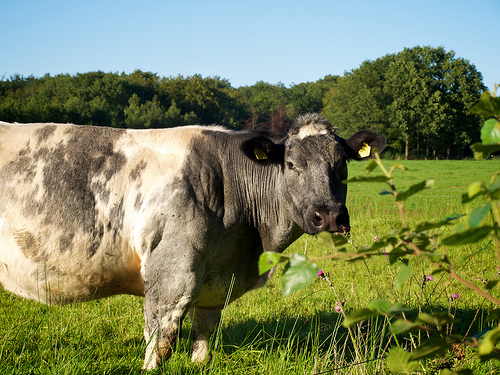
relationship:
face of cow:
[284, 127, 344, 235] [2, 110, 349, 374]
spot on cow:
[130, 154, 153, 183] [2, 110, 349, 374]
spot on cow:
[137, 189, 143, 212] [2, 110, 349, 374]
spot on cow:
[103, 152, 129, 179] [2, 110, 349, 374]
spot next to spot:
[12, 227, 51, 265] [33, 267, 68, 279]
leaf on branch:
[346, 173, 394, 188] [257, 138, 499, 312]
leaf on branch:
[478, 118, 499, 148] [257, 138, 499, 312]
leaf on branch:
[395, 176, 435, 203] [257, 138, 499, 312]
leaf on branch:
[441, 218, 494, 253] [257, 138, 499, 312]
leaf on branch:
[281, 260, 320, 295] [257, 138, 499, 312]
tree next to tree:
[382, 50, 477, 145] [316, 60, 392, 143]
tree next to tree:
[275, 80, 337, 123] [252, 82, 297, 132]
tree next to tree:
[252, 82, 297, 132] [217, 85, 250, 126]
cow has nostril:
[2, 110, 349, 374] [310, 212, 326, 226]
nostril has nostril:
[310, 212, 326, 226] [310, 212, 326, 226]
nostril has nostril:
[310, 212, 326, 226] [334, 210, 349, 229]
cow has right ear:
[2, 110, 349, 374] [239, 137, 287, 170]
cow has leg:
[2, 110, 349, 374] [140, 259, 196, 374]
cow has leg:
[2, 110, 349, 374] [186, 294, 227, 367]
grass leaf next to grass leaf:
[326, 296, 339, 369] [368, 302, 386, 374]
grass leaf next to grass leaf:
[208, 271, 247, 367] [41, 281, 73, 373]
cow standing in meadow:
[2, 110, 349, 374] [0, 156, 497, 374]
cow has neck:
[2, 110, 349, 374] [223, 132, 296, 255]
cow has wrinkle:
[2, 110, 349, 374] [240, 142, 251, 229]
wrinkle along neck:
[265, 166, 276, 232] [223, 132, 296, 255]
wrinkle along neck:
[230, 137, 251, 224] [223, 132, 296, 255]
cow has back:
[2, 110, 349, 374] [3, 122, 205, 248]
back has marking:
[3, 122, 205, 248] [44, 124, 109, 249]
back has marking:
[3, 122, 205, 248] [2, 148, 44, 223]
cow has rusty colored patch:
[2, 110, 349, 374] [100, 250, 150, 296]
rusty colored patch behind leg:
[100, 250, 150, 296] [140, 259, 196, 374]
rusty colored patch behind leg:
[100, 250, 150, 296] [186, 294, 227, 367]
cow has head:
[2, 110, 349, 374] [242, 116, 378, 235]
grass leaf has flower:
[326, 296, 339, 369] [316, 268, 325, 279]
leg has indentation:
[140, 259, 196, 374] [149, 232, 165, 251]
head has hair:
[242, 116, 378, 235] [290, 112, 331, 127]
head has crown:
[242, 116, 378, 235] [296, 122, 330, 140]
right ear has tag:
[239, 137, 287, 170] [254, 146, 268, 161]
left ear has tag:
[340, 132, 388, 159] [358, 142, 371, 161]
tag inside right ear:
[254, 146, 268, 161] [239, 137, 287, 170]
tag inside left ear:
[254, 146, 268, 161] [340, 132, 388, 159]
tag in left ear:
[254, 146, 268, 161] [340, 132, 388, 159]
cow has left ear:
[2, 110, 349, 374] [340, 132, 388, 159]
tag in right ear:
[254, 146, 268, 161] [239, 137, 287, 170]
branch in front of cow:
[257, 138, 499, 312] [2, 110, 349, 374]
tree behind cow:
[217, 85, 250, 126] [2, 110, 349, 374]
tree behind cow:
[252, 82, 297, 132] [2, 110, 349, 374]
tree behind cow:
[275, 80, 337, 123] [2, 110, 349, 374]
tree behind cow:
[316, 60, 392, 143] [2, 110, 349, 374]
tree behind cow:
[382, 50, 477, 145] [2, 110, 349, 374]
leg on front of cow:
[140, 259, 196, 374] [2, 110, 349, 374]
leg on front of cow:
[186, 294, 227, 367] [2, 110, 349, 374]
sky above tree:
[3, 3, 497, 88] [217, 85, 250, 126]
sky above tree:
[3, 3, 497, 88] [252, 82, 297, 132]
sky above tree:
[3, 3, 497, 88] [275, 80, 337, 123]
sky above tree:
[3, 3, 497, 88] [316, 60, 392, 143]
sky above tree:
[3, 3, 497, 88] [382, 50, 477, 145]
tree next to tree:
[217, 85, 250, 126] [252, 82, 297, 132]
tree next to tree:
[275, 80, 337, 123] [316, 60, 392, 143]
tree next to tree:
[316, 60, 392, 143] [382, 50, 477, 145]